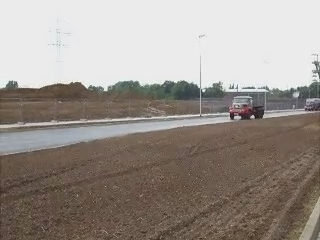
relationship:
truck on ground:
[229, 96, 267, 121] [4, 88, 319, 238]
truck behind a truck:
[304, 101, 320, 112] [229, 96, 267, 121]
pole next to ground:
[197, 35, 204, 119] [4, 88, 319, 238]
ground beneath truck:
[4, 88, 319, 238] [229, 96, 267, 121]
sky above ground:
[2, 3, 320, 91] [4, 88, 319, 238]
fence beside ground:
[0, 95, 319, 126] [4, 88, 319, 238]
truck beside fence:
[229, 96, 267, 121] [0, 95, 319, 126]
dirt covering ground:
[2, 113, 320, 239] [4, 88, 319, 238]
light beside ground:
[197, 34, 207, 116] [4, 88, 319, 238]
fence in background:
[0, 95, 319, 126] [1, 69, 319, 123]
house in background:
[222, 88, 269, 111] [1, 69, 319, 123]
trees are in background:
[87, 79, 224, 100] [1, 69, 319, 123]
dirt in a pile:
[1, 82, 320, 128] [41, 81, 91, 96]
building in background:
[222, 88, 269, 111] [1, 69, 319, 123]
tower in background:
[45, 23, 72, 88] [1, 69, 319, 123]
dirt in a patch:
[1, 82, 320, 128] [6, 101, 212, 120]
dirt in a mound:
[1, 82, 320, 128] [41, 81, 91, 96]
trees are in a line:
[87, 79, 224, 100] [105, 90, 219, 91]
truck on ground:
[304, 101, 320, 112] [4, 88, 319, 238]